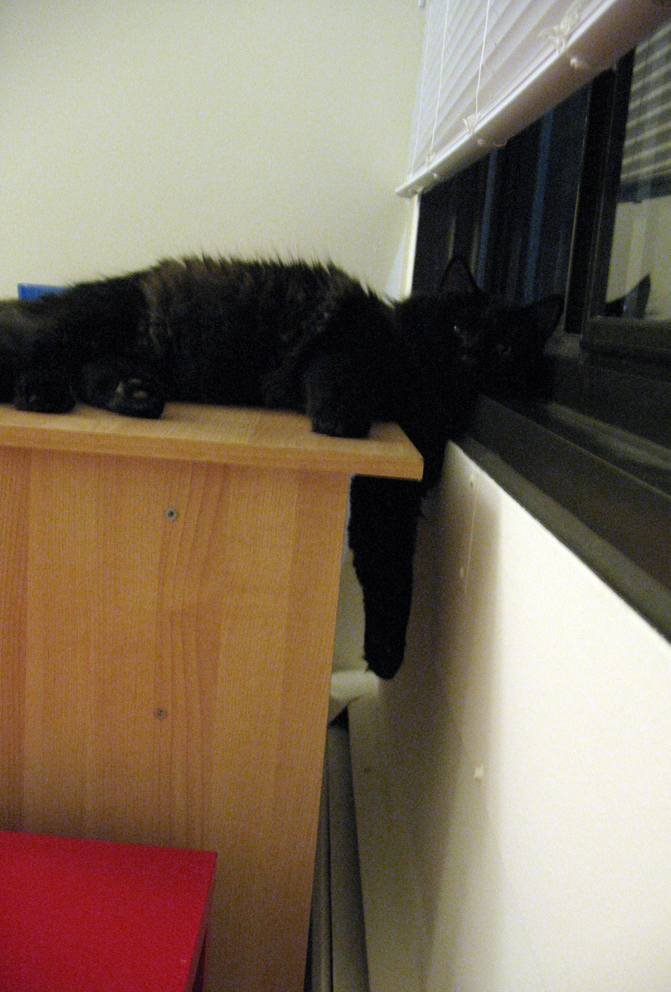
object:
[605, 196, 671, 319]
ground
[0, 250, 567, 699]
cat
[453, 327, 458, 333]
cateye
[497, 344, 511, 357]
cateye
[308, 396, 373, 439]
paw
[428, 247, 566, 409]
cat head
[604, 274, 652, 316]
reflection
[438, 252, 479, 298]
ear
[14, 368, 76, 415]
paw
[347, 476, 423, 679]
cat paw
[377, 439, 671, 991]
wall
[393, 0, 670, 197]
blinds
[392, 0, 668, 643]
window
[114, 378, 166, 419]
paw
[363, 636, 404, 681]
paw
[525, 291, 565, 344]
ear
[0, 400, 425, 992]
desk